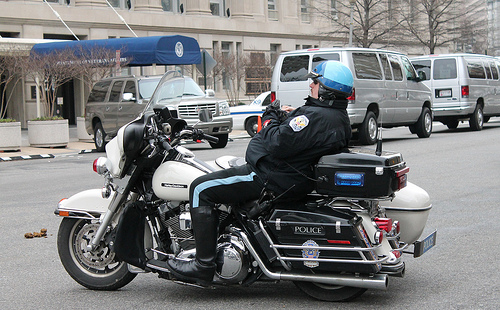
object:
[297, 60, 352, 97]
helmet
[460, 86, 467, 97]
light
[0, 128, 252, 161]
pavement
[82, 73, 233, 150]
cars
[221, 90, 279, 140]
cars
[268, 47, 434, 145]
cars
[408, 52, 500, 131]
cars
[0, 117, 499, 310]
road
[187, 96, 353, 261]
uniform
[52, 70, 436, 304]
motorcycle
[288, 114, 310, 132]
badge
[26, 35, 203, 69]
awning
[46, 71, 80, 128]
doorway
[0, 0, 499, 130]
building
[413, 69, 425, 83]
mirror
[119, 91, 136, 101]
mirror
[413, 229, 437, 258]
license plate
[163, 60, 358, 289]
cop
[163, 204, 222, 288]
boot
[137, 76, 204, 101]
window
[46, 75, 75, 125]
door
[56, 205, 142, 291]
wheel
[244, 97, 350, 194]
jacket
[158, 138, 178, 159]
handle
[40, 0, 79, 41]
pole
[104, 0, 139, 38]
pole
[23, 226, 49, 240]
trash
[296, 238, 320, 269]
sign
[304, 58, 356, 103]
head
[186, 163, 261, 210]
pants